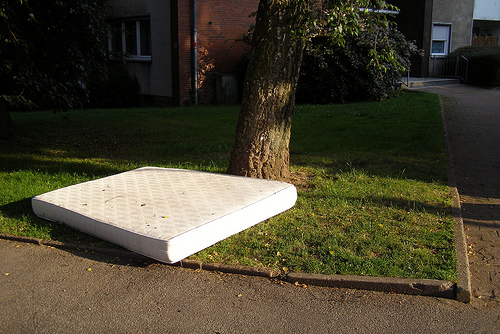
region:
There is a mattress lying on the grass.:
[25, 160, 436, 270]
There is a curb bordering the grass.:
[0, 175, 465, 295]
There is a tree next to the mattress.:
[245, 0, 410, 181]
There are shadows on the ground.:
[0, 85, 495, 251]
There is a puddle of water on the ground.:
[400, 71, 455, 91]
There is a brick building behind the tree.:
[5, 0, 261, 120]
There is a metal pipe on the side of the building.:
[185, 0, 200, 100]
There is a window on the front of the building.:
[110, 10, 165, 65]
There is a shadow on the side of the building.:
[185, 2, 255, 103]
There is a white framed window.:
[421, 23, 451, 64]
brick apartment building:
[100, 0, 497, 107]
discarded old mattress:
[26, 163, 295, 259]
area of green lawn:
[0, 88, 470, 297]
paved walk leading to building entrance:
[413, 92, 497, 332]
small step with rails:
[405, 53, 466, 90]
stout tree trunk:
[227, 3, 365, 188]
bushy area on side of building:
[2, 0, 130, 110]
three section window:
[110, 16, 154, 61]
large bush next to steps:
[292, 5, 420, 100]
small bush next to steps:
[455, 45, 499, 83]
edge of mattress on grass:
[135, 228, 191, 266]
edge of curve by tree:
[427, 260, 482, 305]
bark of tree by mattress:
[227, 63, 317, 203]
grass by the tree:
[300, 214, 422, 269]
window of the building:
[425, 14, 455, 62]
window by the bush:
[98, 15, 168, 60]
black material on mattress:
[100, 173, 150, 214]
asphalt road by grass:
[56, 266, 332, 332]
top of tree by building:
[13, 23, 120, 103]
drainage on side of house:
[184, 13, 214, 99]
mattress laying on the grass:
[19, 158, 317, 275]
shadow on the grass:
[3, 118, 232, 178]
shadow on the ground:
[464, 191, 499, 226]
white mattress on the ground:
[24, 161, 314, 275]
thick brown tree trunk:
[232, 2, 314, 192]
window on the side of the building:
[432, 23, 454, 62]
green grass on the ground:
[5, 108, 453, 283]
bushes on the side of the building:
[193, 23, 386, 109]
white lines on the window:
[98, 21, 156, 63]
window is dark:
[101, 16, 161, 65]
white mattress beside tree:
[39, 144, 299, 265]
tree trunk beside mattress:
[220, 2, 338, 172]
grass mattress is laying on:
[15, 91, 442, 286]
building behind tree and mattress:
[95, 3, 350, 91]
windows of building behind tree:
[90, 12, 153, 61]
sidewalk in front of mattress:
[2, 233, 463, 333]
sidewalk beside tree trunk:
[447, 83, 499, 311]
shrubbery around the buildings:
[7, 1, 495, 102]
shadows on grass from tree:
[24, 79, 471, 218]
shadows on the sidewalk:
[444, 85, 499, 225]